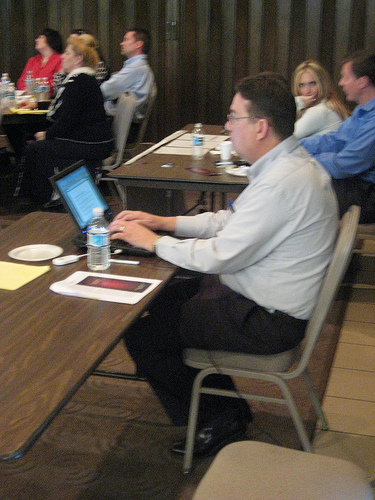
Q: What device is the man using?
A: Laptop.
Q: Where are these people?
A: Conference.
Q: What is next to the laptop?
A: Bottle of water.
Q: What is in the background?
A: Room divider.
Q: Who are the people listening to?
A: Speaker.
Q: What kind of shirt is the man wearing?
A: Dress.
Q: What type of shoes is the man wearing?
A: Dress.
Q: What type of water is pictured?
A: Spring.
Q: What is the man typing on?
A: Laptop.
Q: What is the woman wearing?
A: Black sweater.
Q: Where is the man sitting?
A: Chair.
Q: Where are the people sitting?
A: Table.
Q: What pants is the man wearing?
A: Slacks.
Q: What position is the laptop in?
A: Open.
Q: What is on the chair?
A: Cushion.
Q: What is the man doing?
A: Working.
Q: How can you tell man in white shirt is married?
A: Wedding ring.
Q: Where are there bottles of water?
A: Tables.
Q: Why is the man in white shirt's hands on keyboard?
A: Typing on laptop.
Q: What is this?
A: Conference.